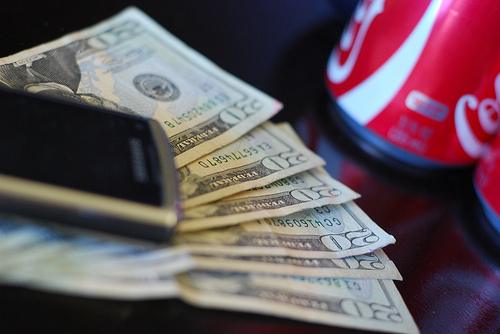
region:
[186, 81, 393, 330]
six 20 dollar bills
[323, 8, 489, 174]
a red soda can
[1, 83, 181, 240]
a black and silver cell phone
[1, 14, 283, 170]
a twenty dollar bill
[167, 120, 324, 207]
a twenty dollar bill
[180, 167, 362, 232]
a twenty dollar bill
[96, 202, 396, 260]
a twenty dollar bill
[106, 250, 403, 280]
a twenty dollar bill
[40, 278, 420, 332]
a twenty dollar bill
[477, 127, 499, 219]
the bottom of a Coca-Cola can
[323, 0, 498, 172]
part of a Coca-Cola can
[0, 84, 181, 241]
a phone on top of money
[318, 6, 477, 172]
a Coca Cola can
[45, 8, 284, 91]
a twenty dollar bill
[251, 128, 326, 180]
a twenty dollar bill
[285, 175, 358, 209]
a twenty dollar bill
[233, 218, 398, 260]
a twenty dollar bill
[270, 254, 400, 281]
a twenty dollar bill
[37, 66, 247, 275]
a cell phone on a bunch of money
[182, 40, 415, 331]
several twenty dollar bills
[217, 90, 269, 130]
the number twenty on a twenty dollar bill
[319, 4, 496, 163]
Can of Coca Cola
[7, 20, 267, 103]
One Twenty dollar bill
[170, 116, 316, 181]
One Twenty dollar bill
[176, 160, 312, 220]
One Twenty Dollar Bill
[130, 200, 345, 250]
One Twenty dollar bill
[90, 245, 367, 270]
One twenty dollar bill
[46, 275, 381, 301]
One Twenty dollar bill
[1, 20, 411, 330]
Six twenty dollar bills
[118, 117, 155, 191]
Name of Cell Phone Brand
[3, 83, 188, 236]
Turned Off Cell Phone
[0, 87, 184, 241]
black and silver cell phone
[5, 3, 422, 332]
a cell phone on a stack of money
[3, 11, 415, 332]
a stack of 20 dollar bills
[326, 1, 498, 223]
two coca cola cans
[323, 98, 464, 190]
bottom of a soda can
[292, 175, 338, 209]
green twenty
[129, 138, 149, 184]
phone logo on the cell phone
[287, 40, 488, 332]
reflections on the table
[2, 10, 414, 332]
pile of money on the table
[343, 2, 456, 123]
white stripe on the soda can